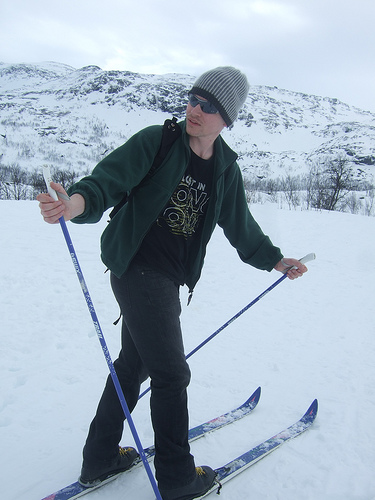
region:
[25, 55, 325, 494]
cross country skier looking backwards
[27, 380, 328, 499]
blue red and white cross country skis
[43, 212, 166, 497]
skinny blue ski pole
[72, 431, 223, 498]
boots of skier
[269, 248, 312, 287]
left hand holding a ski pole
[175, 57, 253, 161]
head and neck of cross country skier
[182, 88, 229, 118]
sunglasses on eyes of cross country skier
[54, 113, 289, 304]
green jacket of cross country skier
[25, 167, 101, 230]
right hand and wrist of cross country skier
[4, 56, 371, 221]
mountains near cross country skiing area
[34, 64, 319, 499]
A man sking in the snow.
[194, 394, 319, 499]
A blue colored ski.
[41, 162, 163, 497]
A blue and white ski pole.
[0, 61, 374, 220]
A mountain of snow.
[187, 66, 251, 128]
Black and gray hat.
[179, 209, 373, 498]
Large area of snow.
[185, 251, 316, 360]
A skinny ski pole.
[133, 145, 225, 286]
A black colored tshirt.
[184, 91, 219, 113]
Pair of dark sunglasses.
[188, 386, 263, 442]
Part of a blue ski.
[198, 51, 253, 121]
Man wearing stocking cap.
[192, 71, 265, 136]
Person's hat is gray and black.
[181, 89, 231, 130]
Sunglasses on person's face.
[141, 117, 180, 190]
Black strap around man's shoulder.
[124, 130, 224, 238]
Man wearing green jacket.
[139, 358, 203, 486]
Person wearing black pants.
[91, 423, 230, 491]
Person standing on 2 blue skis.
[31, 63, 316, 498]
a man on skis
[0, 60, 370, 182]
snow covered mountains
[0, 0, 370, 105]
overcast sky over the snowy landscape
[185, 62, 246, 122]
gray knit cap the skier is wearing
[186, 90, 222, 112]
glasses worn by the skier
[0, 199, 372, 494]
snowy area the skier is in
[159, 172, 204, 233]
the design on the skier's shirt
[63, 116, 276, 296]
the jacket worn by the skier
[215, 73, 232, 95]
man wearing striped hat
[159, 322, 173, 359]
man wearing black pants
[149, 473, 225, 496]
man wearing black sneakers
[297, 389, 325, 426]
tip of left ski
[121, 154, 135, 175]
man wearing green coat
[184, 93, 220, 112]
man wearing black sunglasses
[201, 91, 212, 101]
black stripe on hat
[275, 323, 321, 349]
white snow on ground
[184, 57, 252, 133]
man wearing a knit cap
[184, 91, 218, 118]
man wearing dark sunglasses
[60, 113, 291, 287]
man wearing small jacket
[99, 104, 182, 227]
strap on man's shoulder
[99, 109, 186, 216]
strap on shoulder is black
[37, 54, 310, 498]
man standing on skis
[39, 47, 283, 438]
this is a man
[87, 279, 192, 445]
the pants are black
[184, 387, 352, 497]
these are skis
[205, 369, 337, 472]
the skis are blue and yellow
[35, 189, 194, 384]
the man is holding a ski pole